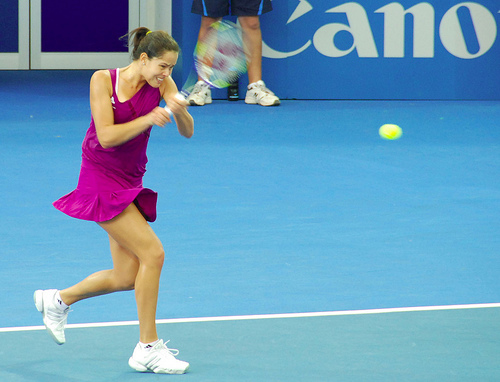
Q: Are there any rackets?
A: Yes, there is a racket.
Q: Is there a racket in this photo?
A: Yes, there is a racket.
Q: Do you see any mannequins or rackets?
A: Yes, there is a racket.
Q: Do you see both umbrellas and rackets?
A: No, there is a racket but no umbrellas.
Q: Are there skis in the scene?
A: No, there are no skis.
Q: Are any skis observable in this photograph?
A: No, there are no skis.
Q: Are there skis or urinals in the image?
A: No, there are no skis or urinals.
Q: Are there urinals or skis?
A: No, there are no skis or urinals.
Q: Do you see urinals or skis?
A: No, there are no skis or urinals.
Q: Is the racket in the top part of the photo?
A: Yes, the racket is in the top of the image.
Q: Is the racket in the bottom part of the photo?
A: No, the racket is in the top of the image.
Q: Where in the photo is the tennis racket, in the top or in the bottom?
A: The tennis racket is in the top of the image.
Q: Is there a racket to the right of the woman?
A: Yes, there is a racket to the right of the woman.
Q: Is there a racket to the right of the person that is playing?
A: Yes, there is a racket to the right of the woman.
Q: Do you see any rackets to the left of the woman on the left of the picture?
A: No, the racket is to the right of the woman.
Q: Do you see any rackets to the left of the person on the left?
A: No, the racket is to the right of the woman.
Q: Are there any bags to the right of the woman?
A: No, there is a racket to the right of the woman.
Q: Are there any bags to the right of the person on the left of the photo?
A: No, there is a racket to the right of the woman.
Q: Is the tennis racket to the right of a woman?
A: Yes, the tennis racket is to the right of a woman.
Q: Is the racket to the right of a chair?
A: No, the racket is to the right of a woman.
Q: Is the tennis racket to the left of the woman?
A: No, the tennis racket is to the right of the woman.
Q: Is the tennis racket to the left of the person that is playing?
A: No, the tennis racket is to the right of the woman.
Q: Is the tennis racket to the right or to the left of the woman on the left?
A: The tennis racket is to the right of the woman.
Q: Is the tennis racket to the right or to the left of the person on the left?
A: The tennis racket is to the right of the woman.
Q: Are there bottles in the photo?
A: Yes, there is a bottle.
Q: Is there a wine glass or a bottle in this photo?
A: Yes, there is a bottle.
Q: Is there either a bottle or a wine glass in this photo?
A: Yes, there is a bottle.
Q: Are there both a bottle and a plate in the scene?
A: No, there is a bottle but no plates.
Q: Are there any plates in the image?
A: No, there are no plates.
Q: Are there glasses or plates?
A: No, there are no plates or glasses.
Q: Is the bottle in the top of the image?
A: Yes, the bottle is in the top of the image.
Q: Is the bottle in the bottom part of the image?
A: No, the bottle is in the top of the image.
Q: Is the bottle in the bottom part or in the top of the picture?
A: The bottle is in the top of the image.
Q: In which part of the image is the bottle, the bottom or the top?
A: The bottle is in the top of the image.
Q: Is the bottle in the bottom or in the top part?
A: The bottle is in the top of the image.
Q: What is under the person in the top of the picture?
A: The bottle is under the person.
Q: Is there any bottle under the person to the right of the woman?
A: Yes, there is a bottle under the person.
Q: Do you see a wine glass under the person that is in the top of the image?
A: No, there is a bottle under the person.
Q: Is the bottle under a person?
A: Yes, the bottle is under a person.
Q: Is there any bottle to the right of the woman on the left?
A: Yes, there is a bottle to the right of the woman.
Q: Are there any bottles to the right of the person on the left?
A: Yes, there is a bottle to the right of the woman.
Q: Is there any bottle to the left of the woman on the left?
A: No, the bottle is to the right of the woman.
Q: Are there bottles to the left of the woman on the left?
A: No, the bottle is to the right of the woman.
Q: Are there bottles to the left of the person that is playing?
A: No, the bottle is to the right of the woman.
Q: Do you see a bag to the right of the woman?
A: No, there is a bottle to the right of the woman.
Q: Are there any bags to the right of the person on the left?
A: No, there is a bottle to the right of the woman.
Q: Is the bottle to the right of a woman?
A: Yes, the bottle is to the right of a woman.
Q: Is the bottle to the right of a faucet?
A: No, the bottle is to the right of a woman.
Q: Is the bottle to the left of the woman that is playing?
A: No, the bottle is to the right of the woman.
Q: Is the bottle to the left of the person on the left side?
A: No, the bottle is to the right of the woman.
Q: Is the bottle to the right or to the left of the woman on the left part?
A: The bottle is to the right of the woman.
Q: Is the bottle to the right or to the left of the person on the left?
A: The bottle is to the right of the woman.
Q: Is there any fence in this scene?
A: No, there are no fences.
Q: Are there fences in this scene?
A: No, there are no fences.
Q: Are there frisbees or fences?
A: No, there are no fences or frisbees.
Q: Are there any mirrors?
A: No, there are no mirrors.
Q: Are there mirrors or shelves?
A: No, there are no mirrors or shelves.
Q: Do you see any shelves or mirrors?
A: No, there are no mirrors or shelves.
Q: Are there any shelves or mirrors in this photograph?
A: No, there are no mirrors or shelves.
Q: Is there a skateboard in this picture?
A: No, there are no skateboards.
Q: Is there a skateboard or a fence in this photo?
A: No, there are no skateboards or fences.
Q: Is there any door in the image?
A: Yes, there are doors.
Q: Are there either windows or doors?
A: Yes, there are doors.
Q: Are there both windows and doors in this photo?
A: No, there are doors but no windows.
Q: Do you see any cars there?
A: No, there are no cars.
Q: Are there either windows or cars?
A: No, there are no cars or windows.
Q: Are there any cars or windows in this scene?
A: No, there are no cars or windows.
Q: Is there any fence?
A: No, there are no fences.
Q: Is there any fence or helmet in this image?
A: No, there are no fences or helmets.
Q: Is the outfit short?
A: Yes, the outfit is short.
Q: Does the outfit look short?
A: Yes, the outfit is short.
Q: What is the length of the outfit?
A: The outfit is short.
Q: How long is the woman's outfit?
A: The outfit is short.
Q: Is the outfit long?
A: No, the outfit is short.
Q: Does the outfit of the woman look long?
A: No, the outfit is short.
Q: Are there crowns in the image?
A: No, there are no crowns.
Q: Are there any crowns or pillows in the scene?
A: No, there are no crowns or pillows.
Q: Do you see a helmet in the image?
A: No, there are no helmets.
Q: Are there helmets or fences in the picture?
A: No, there are no helmets or fences.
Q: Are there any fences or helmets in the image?
A: No, there are no helmets or fences.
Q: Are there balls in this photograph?
A: Yes, there is a ball.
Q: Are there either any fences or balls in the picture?
A: Yes, there is a ball.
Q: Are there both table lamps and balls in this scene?
A: No, there is a ball but no table lamps.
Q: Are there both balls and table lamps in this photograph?
A: No, there is a ball but no table lamps.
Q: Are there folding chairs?
A: No, there are no folding chairs.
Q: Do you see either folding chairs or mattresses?
A: No, there are no folding chairs or mattresses.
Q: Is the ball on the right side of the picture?
A: Yes, the ball is on the right of the image.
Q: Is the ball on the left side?
A: No, the ball is on the right of the image.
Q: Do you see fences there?
A: No, there are no fences.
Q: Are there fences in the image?
A: No, there are no fences.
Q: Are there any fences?
A: No, there are no fences.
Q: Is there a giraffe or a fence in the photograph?
A: No, there are no fences or giraffes.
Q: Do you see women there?
A: Yes, there is a woman.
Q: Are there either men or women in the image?
A: Yes, there is a woman.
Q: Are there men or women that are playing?
A: Yes, the woman is playing.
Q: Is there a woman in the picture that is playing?
A: Yes, there is a woman that is playing.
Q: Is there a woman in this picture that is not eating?
A: Yes, there is a woman that is playing.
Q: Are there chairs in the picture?
A: No, there are no chairs.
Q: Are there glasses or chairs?
A: No, there are no chairs or glasses.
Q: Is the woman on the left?
A: Yes, the woman is on the left of the image.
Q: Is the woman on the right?
A: No, the woman is on the left of the image.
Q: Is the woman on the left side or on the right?
A: The woman is on the left of the image.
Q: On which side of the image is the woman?
A: The woman is on the left of the image.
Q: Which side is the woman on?
A: The woman is on the left of the image.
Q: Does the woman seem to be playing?
A: Yes, the woman is playing.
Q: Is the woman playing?
A: Yes, the woman is playing.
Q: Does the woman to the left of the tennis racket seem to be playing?
A: Yes, the woman is playing.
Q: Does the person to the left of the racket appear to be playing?
A: Yes, the woman is playing.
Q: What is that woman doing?
A: The woman is playing.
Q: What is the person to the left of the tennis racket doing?
A: The woman is playing.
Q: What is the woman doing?
A: The woman is playing.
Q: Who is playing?
A: The woman is playing.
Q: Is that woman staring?
A: No, the woman is playing.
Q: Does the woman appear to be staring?
A: No, the woman is playing.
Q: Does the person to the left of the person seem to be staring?
A: No, the woman is playing.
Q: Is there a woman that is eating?
A: No, there is a woman but she is playing.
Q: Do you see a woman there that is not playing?
A: No, there is a woman but she is playing.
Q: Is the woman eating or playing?
A: The woman is playing.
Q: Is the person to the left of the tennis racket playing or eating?
A: The woman is playing.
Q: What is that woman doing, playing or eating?
A: The woman is playing.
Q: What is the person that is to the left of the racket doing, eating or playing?
A: The woman is playing.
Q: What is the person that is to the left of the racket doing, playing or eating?
A: The woman is playing.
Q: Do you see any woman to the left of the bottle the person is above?
A: Yes, there is a woman to the left of the bottle.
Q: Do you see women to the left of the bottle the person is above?
A: Yes, there is a woman to the left of the bottle.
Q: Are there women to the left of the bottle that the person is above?
A: Yes, there is a woman to the left of the bottle.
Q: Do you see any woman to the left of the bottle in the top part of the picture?
A: Yes, there is a woman to the left of the bottle.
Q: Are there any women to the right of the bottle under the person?
A: No, the woman is to the left of the bottle.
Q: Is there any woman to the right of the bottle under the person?
A: No, the woman is to the left of the bottle.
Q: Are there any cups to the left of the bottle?
A: No, there is a woman to the left of the bottle.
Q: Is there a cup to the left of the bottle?
A: No, there is a woman to the left of the bottle.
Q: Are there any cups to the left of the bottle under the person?
A: No, there is a woman to the left of the bottle.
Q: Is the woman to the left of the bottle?
A: Yes, the woman is to the left of the bottle.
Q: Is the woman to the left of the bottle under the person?
A: Yes, the woman is to the left of the bottle.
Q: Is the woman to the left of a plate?
A: No, the woman is to the left of the bottle.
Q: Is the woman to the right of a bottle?
A: No, the woman is to the left of a bottle.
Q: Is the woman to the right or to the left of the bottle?
A: The woman is to the left of the bottle.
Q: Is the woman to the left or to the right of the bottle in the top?
A: The woman is to the left of the bottle.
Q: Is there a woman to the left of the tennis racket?
A: Yes, there is a woman to the left of the tennis racket.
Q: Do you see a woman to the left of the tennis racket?
A: Yes, there is a woman to the left of the tennis racket.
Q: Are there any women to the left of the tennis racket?
A: Yes, there is a woman to the left of the tennis racket.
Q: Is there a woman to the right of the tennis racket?
A: No, the woman is to the left of the tennis racket.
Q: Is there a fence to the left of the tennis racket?
A: No, there is a woman to the left of the tennis racket.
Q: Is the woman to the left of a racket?
A: Yes, the woman is to the left of a racket.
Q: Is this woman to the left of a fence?
A: No, the woman is to the left of a racket.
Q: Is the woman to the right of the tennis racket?
A: No, the woman is to the left of the tennis racket.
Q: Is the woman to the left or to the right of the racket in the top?
A: The woman is to the left of the tennis racket.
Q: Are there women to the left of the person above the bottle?
A: Yes, there is a woman to the left of the person.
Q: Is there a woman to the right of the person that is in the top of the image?
A: No, the woman is to the left of the person.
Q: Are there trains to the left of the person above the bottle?
A: No, there is a woman to the left of the person.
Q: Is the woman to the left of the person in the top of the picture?
A: Yes, the woman is to the left of the person.